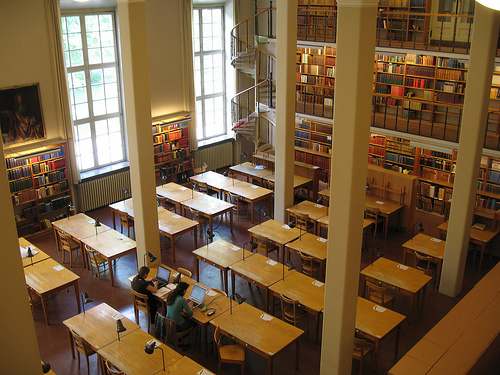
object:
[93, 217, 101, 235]
black lamp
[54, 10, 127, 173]
windows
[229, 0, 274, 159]
staircase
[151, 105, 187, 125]
track lighting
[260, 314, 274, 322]
white object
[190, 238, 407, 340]
table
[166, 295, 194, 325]
shirt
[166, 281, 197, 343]
people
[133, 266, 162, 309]
person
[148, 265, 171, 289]
laptop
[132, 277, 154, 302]
shirt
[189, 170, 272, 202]
desk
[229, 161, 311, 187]
desk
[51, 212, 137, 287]
desk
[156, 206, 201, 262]
desk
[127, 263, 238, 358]
table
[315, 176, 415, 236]
tables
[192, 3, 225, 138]
window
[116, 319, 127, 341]
lamp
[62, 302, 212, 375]
desk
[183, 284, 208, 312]
open laptop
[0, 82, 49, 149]
painting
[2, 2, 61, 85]
wall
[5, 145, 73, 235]
books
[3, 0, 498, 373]
library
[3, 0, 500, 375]
hall